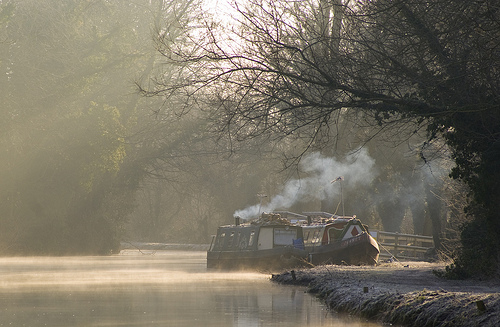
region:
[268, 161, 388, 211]
white smoke in the air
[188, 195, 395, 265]
old boat on the water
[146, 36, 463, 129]
bent tree over boat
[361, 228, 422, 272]
string on side of the land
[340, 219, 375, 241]
white and red square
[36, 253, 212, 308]
murky water in the canal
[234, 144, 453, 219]
rising whitish gray colored smoke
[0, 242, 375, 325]
fog rising from the water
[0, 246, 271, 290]
the sun reflecting on the water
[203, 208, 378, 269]
two old boats on the water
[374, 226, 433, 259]
a fence in the background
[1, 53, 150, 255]
trees with green leaves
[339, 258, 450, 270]
light shining on the ground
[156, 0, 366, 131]
the sky seen through tree branches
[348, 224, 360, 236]
a red diamond shape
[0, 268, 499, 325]
shadows on the ground and water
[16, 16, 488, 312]
boats and tall trees on misty lake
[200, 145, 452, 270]
white smoke from boat chimney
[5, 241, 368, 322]
calm water under white haze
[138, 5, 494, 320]
dark tree with long branches over water and land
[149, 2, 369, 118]
bright sky through branches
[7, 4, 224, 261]
long branches slanting over river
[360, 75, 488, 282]
leaves climbing up trunk and across branch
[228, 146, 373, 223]
steam coming from a boat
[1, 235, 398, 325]
hazy water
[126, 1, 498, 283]
tree over the boat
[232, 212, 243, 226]
steam pipe on a boat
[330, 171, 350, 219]
flag on a boat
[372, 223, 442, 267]
wooden fence by a boat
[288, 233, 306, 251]
blue item on a boat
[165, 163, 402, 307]
this is a boat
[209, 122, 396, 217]
smoke in the air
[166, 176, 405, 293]
the boat is smoking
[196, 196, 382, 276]
Boat on water by the shore.